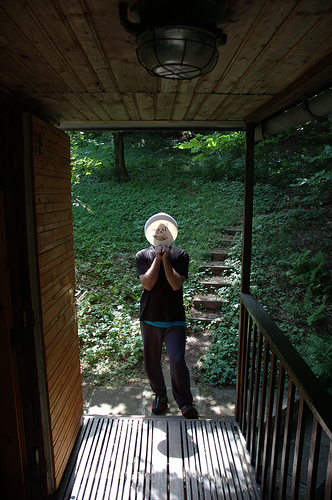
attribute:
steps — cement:
[186, 185, 245, 333]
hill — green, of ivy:
[72, 182, 330, 420]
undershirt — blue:
[142, 319, 189, 330]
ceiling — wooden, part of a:
[2, 2, 331, 129]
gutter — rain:
[249, 85, 331, 143]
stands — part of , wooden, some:
[249, 365, 331, 499]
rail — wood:
[229, 284, 318, 498]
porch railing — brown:
[218, 284, 321, 497]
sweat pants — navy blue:
[137, 311, 204, 405]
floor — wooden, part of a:
[82, 417, 245, 497]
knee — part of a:
[139, 345, 195, 371]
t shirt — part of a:
[130, 239, 193, 322]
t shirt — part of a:
[129, 242, 196, 332]